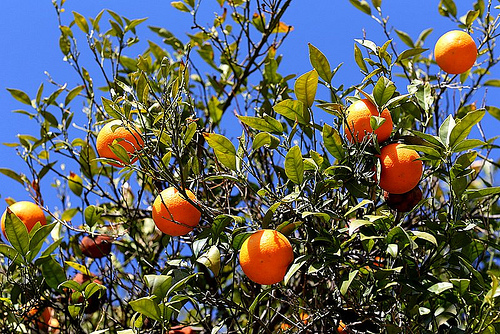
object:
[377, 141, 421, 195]
orange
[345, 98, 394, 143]
orange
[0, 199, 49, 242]
orange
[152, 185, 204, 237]
orange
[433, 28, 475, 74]
oranges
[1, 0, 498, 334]
tree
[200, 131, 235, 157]
leaves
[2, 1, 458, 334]
sky